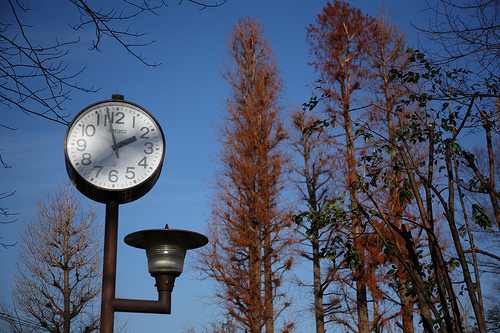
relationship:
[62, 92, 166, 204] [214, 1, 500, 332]
clock near trees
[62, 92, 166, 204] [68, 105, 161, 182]
clock has face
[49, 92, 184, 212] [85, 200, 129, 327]
clock on post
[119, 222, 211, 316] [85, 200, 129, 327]
light on post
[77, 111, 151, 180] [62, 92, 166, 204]
numbers on clock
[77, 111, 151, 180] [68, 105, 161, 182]
numbers on face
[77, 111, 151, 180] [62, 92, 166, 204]
numbers are on clock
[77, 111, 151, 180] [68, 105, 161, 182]
numbers are on face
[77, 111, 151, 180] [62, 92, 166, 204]
numbers on face of clock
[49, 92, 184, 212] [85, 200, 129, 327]
clock on a post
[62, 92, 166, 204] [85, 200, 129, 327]
clock on post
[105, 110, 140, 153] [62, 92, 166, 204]
hands on clock